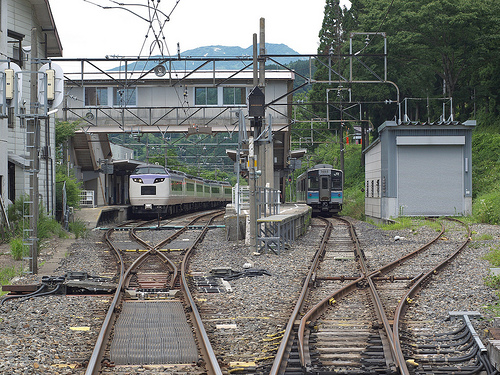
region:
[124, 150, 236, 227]
Train stopped at platform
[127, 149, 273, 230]
train facing forward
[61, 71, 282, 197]
bridge across the platforms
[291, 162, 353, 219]
train leaving the platform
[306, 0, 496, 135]
large trees on embankment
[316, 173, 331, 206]
rear train door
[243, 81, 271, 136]
signal light between platforms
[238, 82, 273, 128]
signal light on a pole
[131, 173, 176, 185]
lights on front of train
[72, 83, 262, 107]
windows on overhead bridge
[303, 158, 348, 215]
the front of a train car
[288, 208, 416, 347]
a set of railroad tracks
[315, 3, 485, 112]
a clump of trees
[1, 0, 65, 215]
a building next to the train tracks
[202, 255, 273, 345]
gravel between the train tracks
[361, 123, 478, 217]
a shed next to the train tracks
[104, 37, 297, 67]
mountain tops off in the distance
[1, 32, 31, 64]
a small window in a building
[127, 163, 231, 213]
a train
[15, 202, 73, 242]
grass beside a building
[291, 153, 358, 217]
Blue train riding on the tracks.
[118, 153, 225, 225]
Tan and purple train riding on the train tracks.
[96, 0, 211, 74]
Antennas by train tracks.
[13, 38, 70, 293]
Train track traffic signal.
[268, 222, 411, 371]
Train track intersection.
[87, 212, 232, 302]
Train track intersection.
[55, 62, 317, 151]
Train track watch building.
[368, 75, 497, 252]
Storage building on train track.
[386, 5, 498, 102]
Green trees with thick foliage.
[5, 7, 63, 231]
Two story tan, wood sided building.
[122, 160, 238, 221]
the train is on the tracks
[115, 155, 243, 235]
the train is white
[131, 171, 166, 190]
the train has eyes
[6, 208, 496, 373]
the tracks are surrounded by gravel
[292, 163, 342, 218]
the train is blue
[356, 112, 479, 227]
the outbuilding is grey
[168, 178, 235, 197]
the white train has windows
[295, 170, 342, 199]
the blue train has windows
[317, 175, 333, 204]
the blue train has a door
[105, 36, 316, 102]
the mountain is tall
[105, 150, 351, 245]
Two trains on the train tracks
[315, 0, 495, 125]
Tall trees are in the background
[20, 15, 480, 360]
This photo was taken in the daytime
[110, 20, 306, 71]
A mountain is in the background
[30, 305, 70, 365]
Gravel is near the train tracks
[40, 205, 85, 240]
Tall weeds are by the building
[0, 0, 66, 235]
A building is by the train tracks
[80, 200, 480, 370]
Four train tracks on the ground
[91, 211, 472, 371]
Two train tracks are on each side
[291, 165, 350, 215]
Front view of the train is blue and gray